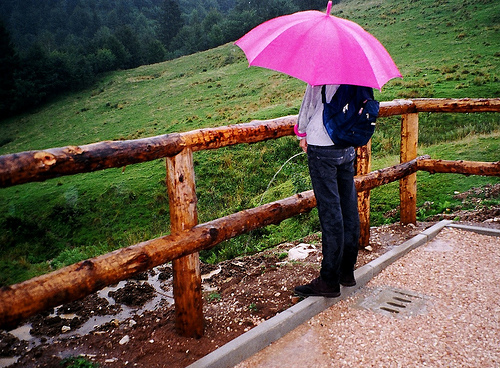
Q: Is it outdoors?
A: Yes, it is outdoors.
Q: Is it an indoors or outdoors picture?
A: It is outdoors.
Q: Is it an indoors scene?
A: No, it is outdoors.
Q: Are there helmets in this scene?
A: No, there are no helmets.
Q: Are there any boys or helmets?
A: No, there are no helmets or boys.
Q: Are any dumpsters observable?
A: No, there are no dumpsters.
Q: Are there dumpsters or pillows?
A: No, there are no dumpsters or pillows.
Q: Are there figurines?
A: No, there are no figurines.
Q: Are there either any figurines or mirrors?
A: No, there are no figurines or mirrors.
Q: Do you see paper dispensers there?
A: No, there are no paper dispensers.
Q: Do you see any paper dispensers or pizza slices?
A: No, there are no paper dispensers or pizza slices.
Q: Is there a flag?
A: No, there are no flags.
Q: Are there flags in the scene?
A: No, there are no flags.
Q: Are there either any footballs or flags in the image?
A: No, there are no flags or footballs.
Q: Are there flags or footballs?
A: No, there are no flags or footballs.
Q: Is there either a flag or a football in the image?
A: No, there are no flags or footballs.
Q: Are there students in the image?
A: No, there are no students.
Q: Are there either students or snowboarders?
A: No, there are no students or snowboarders.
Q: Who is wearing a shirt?
A: The man is wearing a shirt.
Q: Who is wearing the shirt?
A: The man is wearing a shirt.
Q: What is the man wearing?
A: The man is wearing a shirt.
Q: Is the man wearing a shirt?
A: Yes, the man is wearing a shirt.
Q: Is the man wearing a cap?
A: No, the man is wearing a shirt.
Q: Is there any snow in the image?
A: Yes, there is snow.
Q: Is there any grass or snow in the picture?
A: Yes, there is snow.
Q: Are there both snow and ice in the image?
A: Yes, there are both snow and ice.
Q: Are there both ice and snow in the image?
A: Yes, there are both snow and ice.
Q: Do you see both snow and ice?
A: Yes, there are both snow and ice.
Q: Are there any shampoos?
A: No, there are no shampoos.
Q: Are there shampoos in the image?
A: No, there are no shampoos.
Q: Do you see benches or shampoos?
A: No, there are no shampoos or benches.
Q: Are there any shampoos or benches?
A: No, there are no shampoos or benches.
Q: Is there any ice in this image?
A: Yes, there is ice.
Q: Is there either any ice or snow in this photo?
A: Yes, there is ice.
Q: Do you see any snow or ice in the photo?
A: Yes, there is ice.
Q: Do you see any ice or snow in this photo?
A: Yes, there is ice.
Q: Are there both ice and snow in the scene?
A: Yes, there are both ice and snow.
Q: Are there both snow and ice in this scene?
A: Yes, there are both ice and snow.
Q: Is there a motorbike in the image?
A: No, there are no motorcycles.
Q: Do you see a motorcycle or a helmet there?
A: No, there are no motorcycles or helmets.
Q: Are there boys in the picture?
A: No, there are no boys.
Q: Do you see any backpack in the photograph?
A: Yes, there is a backpack.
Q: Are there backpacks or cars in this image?
A: Yes, there is a backpack.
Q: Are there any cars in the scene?
A: No, there are no cars.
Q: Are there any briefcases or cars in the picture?
A: No, there are no cars or briefcases.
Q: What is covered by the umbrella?
A: The backpack is covered by the umbrella.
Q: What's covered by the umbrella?
A: The backpack is covered by the umbrella.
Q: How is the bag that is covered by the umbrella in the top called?
A: The bag is a backpack.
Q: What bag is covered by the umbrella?
A: The bag is a backpack.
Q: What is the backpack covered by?
A: The backpack is covered by the umbrella.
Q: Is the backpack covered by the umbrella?
A: Yes, the backpack is covered by the umbrella.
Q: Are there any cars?
A: No, there are no cars.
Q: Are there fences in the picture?
A: Yes, there is a fence.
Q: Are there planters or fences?
A: Yes, there is a fence.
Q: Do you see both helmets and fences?
A: No, there is a fence but no helmets.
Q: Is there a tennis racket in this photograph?
A: No, there are no rackets.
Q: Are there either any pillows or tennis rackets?
A: No, there are no tennis rackets or pillows.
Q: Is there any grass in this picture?
A: Yes, there is grass.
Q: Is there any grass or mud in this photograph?
A: Yes, there is grass.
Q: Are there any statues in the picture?
A: No, there are no statues.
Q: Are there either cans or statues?
A: No, there are no statues or cans.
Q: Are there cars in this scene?
A: No, there are no cars.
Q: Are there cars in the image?
A: No, there are no cars.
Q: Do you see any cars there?
A: No, there are no cars.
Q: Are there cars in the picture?
A: No, there are no cars.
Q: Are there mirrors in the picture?
A: No, there are no mirrors.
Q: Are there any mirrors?
A: No, there are no mirrors.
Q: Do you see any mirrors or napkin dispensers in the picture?
A: No, there are no mirrors or napkin dispensers.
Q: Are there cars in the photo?
A: No, there are no cars.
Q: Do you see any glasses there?
A: No, there are no glasses.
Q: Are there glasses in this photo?
A: No, there are no glasses.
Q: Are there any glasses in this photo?
A: No, there are no glasses.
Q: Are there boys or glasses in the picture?
A: No, there are no glasses or boys.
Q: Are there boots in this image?
A: Yes, there are boots.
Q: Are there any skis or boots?
A: Yes, there are boots.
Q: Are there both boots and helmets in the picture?
A: No, there are boots but no helmets.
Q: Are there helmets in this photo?
A: No, there are no helmets.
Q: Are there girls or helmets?
A: No, there are no helmets or girls.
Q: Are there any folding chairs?
A: No, there are no folding chairs.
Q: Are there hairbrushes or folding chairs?
A: No, there are no folding chairs or hairbrushes.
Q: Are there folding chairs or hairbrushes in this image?
A: No, there are no folding chairs or hairbrushes.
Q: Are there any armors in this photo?
A: No, there are no armors.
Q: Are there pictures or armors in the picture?
A: No, there are no armors or pictures.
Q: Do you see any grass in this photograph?
A: Yes, there is grass.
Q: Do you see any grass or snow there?
A: Yes, there is grass.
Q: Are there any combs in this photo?
A: No, there are no combs.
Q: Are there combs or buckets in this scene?
A: No, there are no combs or buckets.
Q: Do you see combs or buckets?
A: No, there are no combs or buckets.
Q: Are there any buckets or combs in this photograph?
A: No, there are no combs or buckets.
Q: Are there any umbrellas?
A: Yes, there is an umbrella.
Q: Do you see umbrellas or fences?
A: Yes, there is an umbrella.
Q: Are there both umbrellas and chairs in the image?
A: No, there is an umbrella but no chairs.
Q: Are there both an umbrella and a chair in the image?
A: No, there is an umbrella but no chairs.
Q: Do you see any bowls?
A: No, there are no bowls.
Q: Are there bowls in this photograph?
A: No, there are no bowls.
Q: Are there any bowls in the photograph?
A: No, there are no bowls.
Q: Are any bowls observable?
A: No, there are no bowls.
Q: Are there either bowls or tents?
A: No, there are no bowls or tents.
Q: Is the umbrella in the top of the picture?
A: Yes, the umbrella is in the top of the image.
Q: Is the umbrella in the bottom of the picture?
A: No, the umbrella is in the top of the image.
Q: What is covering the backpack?
A: The umbrella is covering the backpack.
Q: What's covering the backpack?
A: The umbrella is covering the backpack.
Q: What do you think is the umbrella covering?
A: The umbrella is covering the backpack.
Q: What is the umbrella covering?
A: The umbrella is covering the backpack.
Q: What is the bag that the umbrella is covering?
A: The bag is a backpack.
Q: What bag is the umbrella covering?
A: The umbrella is covering the backpack.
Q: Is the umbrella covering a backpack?
A: Yes, the umbrella is covering a backpack.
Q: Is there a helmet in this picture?
A: No, there are no helmets.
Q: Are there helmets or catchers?
A: No, there are no helmets or catchers.